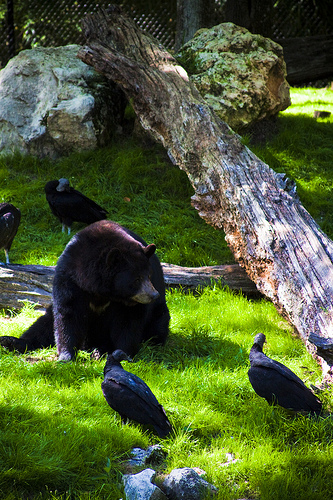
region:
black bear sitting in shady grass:
[3, 216, 191, 361]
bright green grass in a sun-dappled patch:
[197, 294, 236, 324]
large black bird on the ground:
[231, 325, 324, 422]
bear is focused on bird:
[6, 211, 326, 442]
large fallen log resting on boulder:
[84, 51, 301, 197]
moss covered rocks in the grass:
[123, 455, 237, 492]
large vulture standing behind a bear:
[40, 171, 110, 238]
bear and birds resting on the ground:
[6, 138, 318, 450]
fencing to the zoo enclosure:
[28, 2, 73, 42]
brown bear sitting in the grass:
[47, 216, 172, 360]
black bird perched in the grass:
[244, 330, 328, 415]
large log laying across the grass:
[76, 13, 330, 378]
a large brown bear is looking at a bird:
[52, 218, 167, 366]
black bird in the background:
[44, 170, 112, 241]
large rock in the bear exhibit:
[168, 25, 286, 135]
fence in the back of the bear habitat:
[1, 3, 331, 84]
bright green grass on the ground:
[1, 147, 331, 494]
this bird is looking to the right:
[249, 333, 325, 414]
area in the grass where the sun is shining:
[0, 290, 330, 473]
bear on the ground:
[3, 226, 172, 359]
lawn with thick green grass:
[12, 162, 325, 443]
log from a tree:
[147, 68, 315, 247]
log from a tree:
[184, 253, 242, 294]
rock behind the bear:
[4, 44, 127, 166]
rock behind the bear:
[189, 23, 294, 126]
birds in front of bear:
[89, 326, 309, 431]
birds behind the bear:
[3, 169, 103, 240]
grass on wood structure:
[4, 310, 40, 340]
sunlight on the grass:
[290, 86, 318, 112]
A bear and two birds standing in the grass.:
[103, 321, 140, 360]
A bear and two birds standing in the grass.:
[34, 474, 41, 496]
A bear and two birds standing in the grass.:
[113, 454, 137, 492]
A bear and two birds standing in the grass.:
[201, 440, 211, 490]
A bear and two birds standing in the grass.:
[236, 349, 329, 381]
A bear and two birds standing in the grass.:
[208, 290, 222, 390]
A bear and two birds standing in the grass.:
[42, 276, 75, 414]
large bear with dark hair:
[39, 214, 192, 370]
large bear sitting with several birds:
[36, 212, 195, 370]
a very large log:
[77, 4, 332, 377]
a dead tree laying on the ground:
[77, 12, 331, 364]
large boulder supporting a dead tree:
[1, 40, 134, 165]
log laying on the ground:
[164, 259, 286, 293]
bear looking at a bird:
[40, 211, 196, 369]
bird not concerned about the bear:
[84, 338, 196, 445]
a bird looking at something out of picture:
[236, 326, 331, 421]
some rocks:
[109, 445, 224, 499]